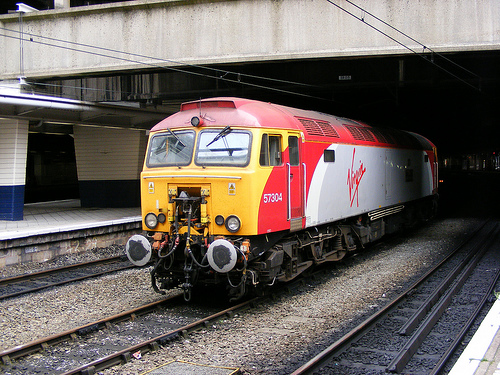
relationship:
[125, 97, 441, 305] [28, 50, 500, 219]
train emerging from tunnel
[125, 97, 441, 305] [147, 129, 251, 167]
train has windows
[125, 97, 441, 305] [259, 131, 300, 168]
train has windows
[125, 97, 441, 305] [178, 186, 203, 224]
train has opening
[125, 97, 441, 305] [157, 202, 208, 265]
train has tubing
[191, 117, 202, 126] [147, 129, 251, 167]
light above windows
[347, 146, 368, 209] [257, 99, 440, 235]
name on side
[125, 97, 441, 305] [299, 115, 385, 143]
train has vents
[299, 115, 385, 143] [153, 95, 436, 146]
vents on roof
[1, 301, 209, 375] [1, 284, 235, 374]
rails in tracks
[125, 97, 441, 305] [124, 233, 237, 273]
train has bumper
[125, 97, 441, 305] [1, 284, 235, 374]
train has tracks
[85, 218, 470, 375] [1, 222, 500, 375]
gravel between tracks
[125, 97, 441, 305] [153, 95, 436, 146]
train has roof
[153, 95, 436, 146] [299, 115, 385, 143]
roof has vents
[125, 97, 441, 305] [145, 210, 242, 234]
train has headlights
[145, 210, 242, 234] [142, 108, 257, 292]
headlights on front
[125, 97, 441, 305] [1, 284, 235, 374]
train on tracks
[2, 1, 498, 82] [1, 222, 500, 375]
overpass above tracks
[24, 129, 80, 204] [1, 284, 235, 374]
building next to tracks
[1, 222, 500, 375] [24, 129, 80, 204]
tracks next to building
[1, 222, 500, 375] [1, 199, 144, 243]
tracks by platform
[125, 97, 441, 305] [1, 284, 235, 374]
train sitting on tracks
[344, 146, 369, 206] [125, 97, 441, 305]
logo on side of train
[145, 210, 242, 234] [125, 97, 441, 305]
headlights on front of train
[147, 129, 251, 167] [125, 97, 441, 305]
windows on front of train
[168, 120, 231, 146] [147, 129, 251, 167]
wipers on windows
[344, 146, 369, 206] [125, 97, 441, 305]
logo written on train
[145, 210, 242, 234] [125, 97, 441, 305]
headlights on train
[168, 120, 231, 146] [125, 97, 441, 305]
wipers on train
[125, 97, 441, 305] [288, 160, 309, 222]
train has railing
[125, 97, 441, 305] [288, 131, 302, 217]
train has door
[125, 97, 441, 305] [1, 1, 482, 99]
train has power lines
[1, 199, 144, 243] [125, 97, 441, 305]
platform for train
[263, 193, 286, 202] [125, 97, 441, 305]
number on train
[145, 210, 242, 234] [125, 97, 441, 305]
headlights in front of train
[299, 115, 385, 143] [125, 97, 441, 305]
vents on side of train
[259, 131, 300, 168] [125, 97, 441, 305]
windows on side of train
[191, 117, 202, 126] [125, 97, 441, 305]
light on top of engine